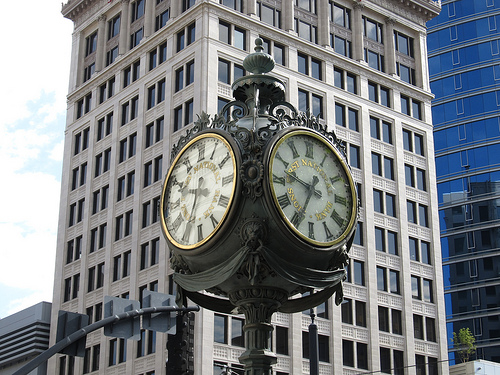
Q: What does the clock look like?
A: The clock is metal with clear glass.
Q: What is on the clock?
A: There are two faces on the clock.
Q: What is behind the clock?
A: There is a building behind the clock.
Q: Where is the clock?
A: The clock is in front of the building.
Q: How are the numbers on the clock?
A: The numbers are roman numeral.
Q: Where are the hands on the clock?
A: The hands are on the nine and the seven.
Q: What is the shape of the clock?
A: The clock is solid and round.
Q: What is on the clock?
A: There is a design on the clock.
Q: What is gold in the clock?
A: The letters are gold.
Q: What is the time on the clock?
A: The time is 9:35.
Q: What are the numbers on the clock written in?
A: Roman numerals.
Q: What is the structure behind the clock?
A: Building.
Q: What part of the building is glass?
A: Windows.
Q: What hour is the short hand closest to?
A: 9.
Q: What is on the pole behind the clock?
A: Signs.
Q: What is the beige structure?
A: Building.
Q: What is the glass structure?
A: Building.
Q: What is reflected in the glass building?
A: The beige building.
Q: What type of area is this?
A: City.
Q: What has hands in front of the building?
A: A clock.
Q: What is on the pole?
A: Clocks.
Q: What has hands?
A: The clock.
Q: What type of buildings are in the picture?
A: Skyscrapers.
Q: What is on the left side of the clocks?
A: Traffic signs.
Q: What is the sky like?
A: Cloudy.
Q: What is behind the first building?
A: A second building.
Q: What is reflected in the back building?
A: The building in the front.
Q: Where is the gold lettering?
A: On the clock faces.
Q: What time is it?
A: 9:35.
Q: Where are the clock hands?
A: On the clock faces.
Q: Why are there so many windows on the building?
A: So that the people inside can see out.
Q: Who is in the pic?
A: No one.